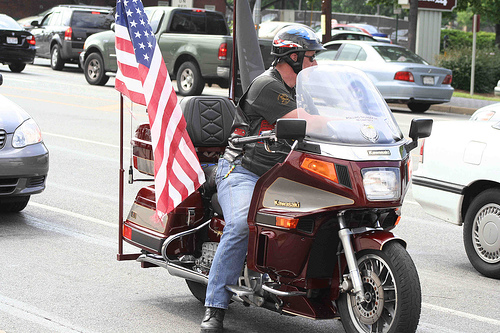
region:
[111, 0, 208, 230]
American flag on the back of the motorcycle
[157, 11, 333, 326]
Man riding the motorcycle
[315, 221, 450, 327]
Front wheel of the motorcycle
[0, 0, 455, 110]
Vehicles in the background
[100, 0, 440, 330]
Man riding motorcycle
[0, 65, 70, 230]
Car trailing behind motorcycle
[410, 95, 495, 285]
Vehicle adjacent to the motorcycle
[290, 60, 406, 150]
Protective windshield for motorcycle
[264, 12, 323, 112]
Man wearing motorcycle helmet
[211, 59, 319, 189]
Man wearing leather jacket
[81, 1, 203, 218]
American flag on the back of a motorcycle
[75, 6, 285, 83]
Green pick-up truck on the road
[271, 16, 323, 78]
Man wearing a motorcycle helmet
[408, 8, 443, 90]
Green sign post on side of road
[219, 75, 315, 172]
Man wearing a black leather vest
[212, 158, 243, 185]
Rainbow colored key ring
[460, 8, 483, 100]
Metal sign post on grass near road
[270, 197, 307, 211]
Gold lettering on motorcycle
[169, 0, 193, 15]
Black and white traffic sign behind truck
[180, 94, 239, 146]
Black leather motorcycle seat back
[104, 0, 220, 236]
American flag on motorcycle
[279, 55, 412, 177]
Front wind screen of motorcycle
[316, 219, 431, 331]
Front wheel of motorcycle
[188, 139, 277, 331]
Man on motorclyce in blue jeans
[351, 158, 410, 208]
Front headlight of motorcycle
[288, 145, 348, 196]
Right yellow turn signal of motorcycle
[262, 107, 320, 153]
Right side mirror of motorcycle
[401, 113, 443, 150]
Left side mirror of motorcycle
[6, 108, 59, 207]
Left front finder of motorcycle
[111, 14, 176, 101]
an American flag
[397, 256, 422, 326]
front tire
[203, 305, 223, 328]
mans shoe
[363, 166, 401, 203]
headlight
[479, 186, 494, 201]
tire on a car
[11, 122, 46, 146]
headlight on a car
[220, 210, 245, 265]
the man is wearing jeans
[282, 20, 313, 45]
man is wearing a helmet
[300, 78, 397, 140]
windshield of the motorcycle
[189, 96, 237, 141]
a black seat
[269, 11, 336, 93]
Red white and blue helmet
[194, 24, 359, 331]
Man looking at the traffic on the right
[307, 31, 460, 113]
Small silver car parked on curb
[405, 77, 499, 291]
Small white car driving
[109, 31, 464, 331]
Burgundy and black motorcycle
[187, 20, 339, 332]
Man wearing blue jeans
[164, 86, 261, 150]
Black seat for motorcycle rider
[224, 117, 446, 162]
Two black side view mirrors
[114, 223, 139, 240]
Orange reflector on back of motorcycle